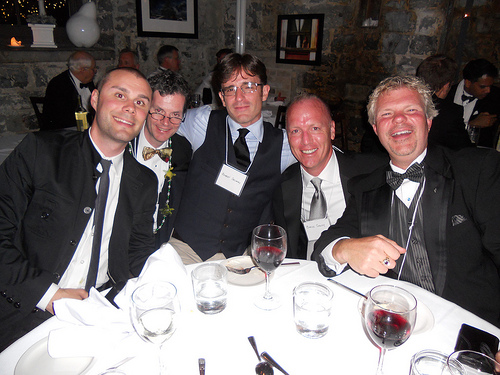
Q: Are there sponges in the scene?
A: No, there are no sponges.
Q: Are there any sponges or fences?
A: No, there are no sponges or fences.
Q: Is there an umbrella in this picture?
A: No, there are no umbrellas.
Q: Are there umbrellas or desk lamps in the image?
A: No, there are no umbrellas or desk lamps.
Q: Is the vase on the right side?
A: No, the vase is on the left of the image.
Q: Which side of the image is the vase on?
A: The vase is on the left of the image.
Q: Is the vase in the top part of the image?
A: Yes, the vase is in the top of the image.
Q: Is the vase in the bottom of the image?
A: No, the vase is in the top of the image.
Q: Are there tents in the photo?
A: No, there are no tents.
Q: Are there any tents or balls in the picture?
A: No, there are no tents or balls.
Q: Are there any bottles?
A: No, there are no bottles.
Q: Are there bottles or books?
A: No, there are no bottles or books.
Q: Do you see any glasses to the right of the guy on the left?
A: Yes, there are glasses to the right of the guy.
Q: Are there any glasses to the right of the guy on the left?
A: Yes, there are glasses to the right of the guy.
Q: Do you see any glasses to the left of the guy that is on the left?
A: No, the glasses are to the right of the guy.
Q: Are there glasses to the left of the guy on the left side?
A: No, the glasses are to the right of the guy.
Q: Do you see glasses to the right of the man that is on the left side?
A: Yes, there are glasses to the right of the man.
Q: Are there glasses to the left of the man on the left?
A: No, the glasses are to the right of the man.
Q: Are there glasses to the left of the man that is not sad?
A: Yes, there are glasses to the left of the man.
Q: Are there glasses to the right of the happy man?
A: No, the glasses are to the left of the man.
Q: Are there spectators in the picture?
A: No, there are no spectators.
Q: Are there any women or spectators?
A: No, there are no spectators or women.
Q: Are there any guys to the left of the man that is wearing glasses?
A: Yes, there is a guy to the left of the man.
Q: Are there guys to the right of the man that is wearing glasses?
A: No, the guy is to the left of the man.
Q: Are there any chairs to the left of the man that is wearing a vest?
A: No, there is a guy to the left of the man.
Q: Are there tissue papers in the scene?
A: No, there are no tissue papers.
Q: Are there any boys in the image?
A: No, there are no boys.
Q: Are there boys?
A: No, there are no boys.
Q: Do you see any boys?
A: No, there are no boys.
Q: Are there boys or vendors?
A: No, there are no boys or vendors.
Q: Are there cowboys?
A: No, there are no cowboys.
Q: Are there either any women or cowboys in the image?
A: No, there are no cowboys or women.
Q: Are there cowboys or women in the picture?
A: No, there are no cowboys or women.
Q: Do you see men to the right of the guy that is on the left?
A: Yes, there is a man to the right of the guy.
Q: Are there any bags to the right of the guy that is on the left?
A: No, there is a man to the right of the guy.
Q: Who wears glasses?
A: The man wears glasses.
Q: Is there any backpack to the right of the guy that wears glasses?
A: No, there is a man to the right of the guy.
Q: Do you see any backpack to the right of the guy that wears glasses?
A: No, there is a man to the right of the guy.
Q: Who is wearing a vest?
A: The man is wearing a vest.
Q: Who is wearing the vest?
A: The man is wearing a vest.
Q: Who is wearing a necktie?
A: The man is wearing a necktie.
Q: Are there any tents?
A: No, there are no tents.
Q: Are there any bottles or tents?
A: No, there are no tents or bottles.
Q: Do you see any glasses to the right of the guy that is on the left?
A: Yes, there are glasses to the right of the guy.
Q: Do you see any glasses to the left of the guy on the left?
A: No, the glasses are to the right of the guy.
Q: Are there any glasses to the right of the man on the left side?
A: Yes, there are glasses to the right of the man.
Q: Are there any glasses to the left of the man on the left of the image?
A: No, the glasses are to the right of the man.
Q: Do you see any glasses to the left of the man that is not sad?
A: Yes, there are glasses to the left of the man.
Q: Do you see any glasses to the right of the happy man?
A: No, the glasses are to the left of the man.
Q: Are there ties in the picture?
A: Yes, there is a tie.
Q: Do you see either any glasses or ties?
A: Yes, there is a tie.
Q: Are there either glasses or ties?
A: Yes, there is a tie.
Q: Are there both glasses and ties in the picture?
A: Yes, there are both a tie and glasses.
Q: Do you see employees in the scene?
A: No, there are no employees.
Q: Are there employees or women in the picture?
A: No, there are no employees or women.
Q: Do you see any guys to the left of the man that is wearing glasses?
A: Yes, there is a guy to the left of the man.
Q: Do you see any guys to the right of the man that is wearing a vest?
A: No, the guy is to the left of the man.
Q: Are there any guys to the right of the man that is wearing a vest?
A: No, the guy is to the left of the man.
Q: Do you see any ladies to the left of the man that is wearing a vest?
A: No, there is a guy to the left of the man.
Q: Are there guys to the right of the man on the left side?
A: Yes, there is a guy to the right of the man.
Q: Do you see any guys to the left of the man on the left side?
A: No, the guy is to the right of the man.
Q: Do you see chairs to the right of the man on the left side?
A: No, there is a guy to the right of the man.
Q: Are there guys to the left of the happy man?
A: Yes, there is a guy to the left of the man.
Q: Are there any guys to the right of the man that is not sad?
A: No, the guy is to the left of the man.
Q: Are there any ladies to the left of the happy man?
A: No, there is a guy to the left of the man.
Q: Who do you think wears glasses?
A: The guy wears glasses.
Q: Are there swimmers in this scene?
A: No, there are no swimmers.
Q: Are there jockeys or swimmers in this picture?
A: No, there are no swimmers or jockeys.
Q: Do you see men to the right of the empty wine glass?
A: Yes, there is a man to the right of the wine glass.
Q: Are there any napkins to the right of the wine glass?
A: No, there is a man to the right of the wine glass.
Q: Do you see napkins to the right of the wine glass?
A: No, there is a man to the right of the wine glass.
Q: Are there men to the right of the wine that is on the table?
A: Yes, there is a man to the right of the wine.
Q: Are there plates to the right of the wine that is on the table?
A: No, there is a man to the right of the wine.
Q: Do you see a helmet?
A: No, there are no helmets.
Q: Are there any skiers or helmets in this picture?
A: No, there are no helmets or skiers.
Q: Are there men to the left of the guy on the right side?
A: Yes, there is a man to the left of the guy.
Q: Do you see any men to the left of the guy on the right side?
A: Yes, there is a man to the left of the guy.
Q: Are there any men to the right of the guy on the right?
A: No, the man is to the left of the guy.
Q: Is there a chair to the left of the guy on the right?
A: No, there is a man to the left of the guy.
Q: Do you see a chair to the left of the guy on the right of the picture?
A: No, there is a man to the left of the guy.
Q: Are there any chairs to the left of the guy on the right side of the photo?
A: No, there is a man to the left of the guy.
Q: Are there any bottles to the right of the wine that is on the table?
A: No, there is a man to the right of the wine.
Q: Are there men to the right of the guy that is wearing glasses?
A: Yes, there is a man to the right of the guy.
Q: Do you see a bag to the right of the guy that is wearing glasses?
A: No, there is a man to the right of the guy.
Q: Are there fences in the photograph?
A: No, there are no fences.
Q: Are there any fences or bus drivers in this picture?
A: No, there are no fences or bus drivers.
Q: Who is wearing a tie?
A: The man is wearing a tie.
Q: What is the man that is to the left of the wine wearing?
A: The man is wearing a tie.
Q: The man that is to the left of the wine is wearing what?
A: The man is wearing a tie.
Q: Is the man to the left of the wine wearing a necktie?
A: Yes, the man is wearing a necktie.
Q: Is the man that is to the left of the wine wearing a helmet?
A: No, the man is wearing a necktie.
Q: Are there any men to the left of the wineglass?
A: Yes, there is a man to the left of the wineglass.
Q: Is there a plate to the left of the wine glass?
A: No, there is a man to the left of the wine glass.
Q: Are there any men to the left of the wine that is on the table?
A: Yes, there is a man to the left of the wine.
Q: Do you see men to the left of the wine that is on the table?
A: Yes, there is a man to the left of the wine.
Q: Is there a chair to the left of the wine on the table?
A: No, there is a man to the left of the wine.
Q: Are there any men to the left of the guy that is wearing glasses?
A: Yes, there is a man to the left of the guy.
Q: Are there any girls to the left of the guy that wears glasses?
A: No, there is a man to the left of the guy.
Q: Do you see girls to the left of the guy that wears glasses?
A: No, there is a man to the left of the guy.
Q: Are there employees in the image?
A: No, there are no employees.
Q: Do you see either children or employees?
A: No, there are no employees or children.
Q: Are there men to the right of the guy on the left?
A: Yes, there is a man to the right of the guy.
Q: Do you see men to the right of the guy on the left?
A: Yes, there is a man to the right of the guy.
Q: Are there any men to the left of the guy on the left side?
A: No, the man is to the right of the guy.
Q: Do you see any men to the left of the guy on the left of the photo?
A: No, the man is to the right of the guy.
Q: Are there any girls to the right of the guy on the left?
A: No, there is a man to the right of the guy.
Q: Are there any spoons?
A: Yes, there is a spoon.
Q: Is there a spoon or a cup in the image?
A: Yes, there is a spoon.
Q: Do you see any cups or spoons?
A: Yes, there is a spoon.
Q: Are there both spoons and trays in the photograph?
A: No, there is a spoon but no trays.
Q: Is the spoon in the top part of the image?
A: No, the spoon is in the bottom of the image.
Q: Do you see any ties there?
A: Yes, there is a tie.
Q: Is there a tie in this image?
A: Yes, there is a tie.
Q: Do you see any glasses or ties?
A: Yes, there is a tie.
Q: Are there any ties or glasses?
A: Yes, there is a tie.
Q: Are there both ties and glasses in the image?
A: Yes, there are both a tie and glasses.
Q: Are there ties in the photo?
A: Yes, there is a tie.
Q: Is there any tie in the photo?
A: Yes, there is a tie.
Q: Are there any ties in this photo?
A: Yes, there is a tie.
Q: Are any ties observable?
A: Yes, there is a tie.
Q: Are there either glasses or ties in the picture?
A: Yes, there is a tie.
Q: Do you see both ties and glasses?
A: Yes, there are both a tie and glasses.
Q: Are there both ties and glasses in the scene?
A: Yes, there are both a tie and glasses.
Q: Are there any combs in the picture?
A: No, there are no combs.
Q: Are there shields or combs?
A: No, there are no combs or shields.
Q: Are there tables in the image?
A: Yes, there is a table.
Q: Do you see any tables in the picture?
A: Yes, there is a table.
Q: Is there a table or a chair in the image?
A: Yes, there is a table.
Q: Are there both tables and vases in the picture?
A: Yes, there are both a table and a vase.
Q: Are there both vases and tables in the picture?
A: Yes, there are both a table and a vase.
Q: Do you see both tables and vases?
A: Yes, there are both a table and a vase.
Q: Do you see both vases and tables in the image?
A: Yes, there are both a table and a vase.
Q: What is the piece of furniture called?
A: The piece of furniture is a table.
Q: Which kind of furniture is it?
A: The piece of furniture is a table.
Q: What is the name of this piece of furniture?
A: This is a table.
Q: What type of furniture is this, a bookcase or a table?
A: This is a table.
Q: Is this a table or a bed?
A: This is a table.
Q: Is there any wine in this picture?
A: Yes, there is wine.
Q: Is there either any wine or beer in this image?
A: Yes, there is wine.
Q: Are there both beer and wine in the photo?
A: No, there is wine but no beer.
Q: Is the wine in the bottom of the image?
A: Yes, the wine is in the bottom of the image.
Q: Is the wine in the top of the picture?
A: No, the wine is in the bottom of the image.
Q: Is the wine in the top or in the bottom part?
A: The wine is in the bottom of the image.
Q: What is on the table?
A: The wine is on the table.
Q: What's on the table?
A: The wine is on the table.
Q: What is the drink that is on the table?
A: The drink is wine.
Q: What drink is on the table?
A: The drink is wine.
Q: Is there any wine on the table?
A: Yes, there is wine on the table.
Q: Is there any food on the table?
A: No, there is wine on the table.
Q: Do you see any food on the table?
A: No, there is wine on the table.